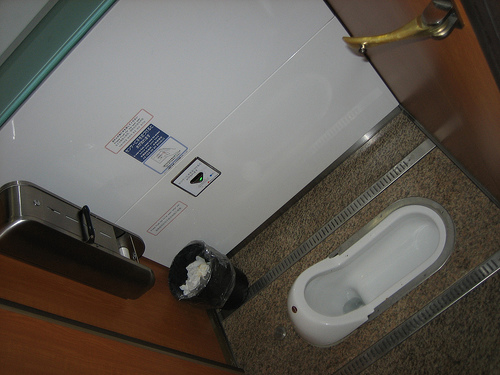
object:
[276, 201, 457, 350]
toilet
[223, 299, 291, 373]
floor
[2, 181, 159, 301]
toilet paper holder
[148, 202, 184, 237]
signs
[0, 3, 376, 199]
wall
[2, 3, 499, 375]
bathroom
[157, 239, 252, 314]
trash can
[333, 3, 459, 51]
wall mount hook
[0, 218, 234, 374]
wall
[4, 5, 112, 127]
beam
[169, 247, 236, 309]
plastic bag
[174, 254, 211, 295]
garbage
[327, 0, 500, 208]
door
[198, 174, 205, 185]
light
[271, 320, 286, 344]
flush button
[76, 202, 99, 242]
lever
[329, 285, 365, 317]
water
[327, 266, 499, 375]
track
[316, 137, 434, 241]
track